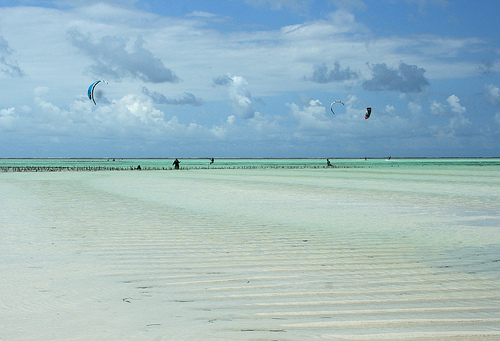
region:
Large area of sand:
[8, 168, 499, 339]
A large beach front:
[3, 168, 498, 336]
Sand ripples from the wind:
[122, 222, 499, 332]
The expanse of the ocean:
[2, 155, 496, 169]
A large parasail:
[85, 78, 102, 105]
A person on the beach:
[168, 157, 183, 167]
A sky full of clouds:
[3, 0, 497, 153]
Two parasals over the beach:
[322, 98, 378, 121]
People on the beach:
[134, 157, 351, 173]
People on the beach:
[86, 77, 388, 174]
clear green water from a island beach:
[5, 157, 497, 167]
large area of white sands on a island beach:
[4, 172, 496, 337]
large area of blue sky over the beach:
[2, 1, 497, 156]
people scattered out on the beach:
[105, 156, 398, 168]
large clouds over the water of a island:
[5, 76, 496, 142]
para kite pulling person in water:
[87, 78, 104, 104]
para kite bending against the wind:
[327, 100, 343, 115]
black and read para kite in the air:
[362, 106, 372, 118]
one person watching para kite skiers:
[172, 158, 179, 168]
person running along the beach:
[325, 158, 332, 165]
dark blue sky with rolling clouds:
[0, 0, 496, 178]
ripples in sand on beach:
[1, 154, 498, 339]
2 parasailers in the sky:
[74, 53, 428, 150]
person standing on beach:
[91, 140, 219, 180]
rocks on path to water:
[3, 155, 173, 194]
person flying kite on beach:
[242, 90, 403, 177]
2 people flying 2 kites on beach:
[65, 68, 230, 180]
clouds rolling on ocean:
[2, 4, 494, 241]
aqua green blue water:
[0, 133, 499, 185]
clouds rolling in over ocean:
[3, 16, 494, 166]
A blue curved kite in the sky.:
[89, 74, 104, 113]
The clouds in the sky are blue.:
[82, 34, 164, 74]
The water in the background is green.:
[48, 160, 94, 167]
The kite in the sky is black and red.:
[364, 105, 374, 121]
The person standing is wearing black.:
[170, 157, 185, 169]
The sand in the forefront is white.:
[121, 256, 251, 307]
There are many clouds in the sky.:
[137, 58, 320, 134]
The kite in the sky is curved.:
[322, 95, 350, 118]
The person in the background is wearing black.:
[323, 158, 336, 169]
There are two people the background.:
[103, 156, 123, 164]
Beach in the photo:
[108, 212, 276, 261]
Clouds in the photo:
[167, 30, 283, 97]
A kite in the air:
[66, 71, 111, 111]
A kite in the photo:
[316, 81, 394, 126]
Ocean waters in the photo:
[249, 150, 306, 170]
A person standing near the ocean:
[162, 150, 194, 177]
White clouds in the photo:
[135, 47, 212, 129]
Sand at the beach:
[33, 217, 113, 294]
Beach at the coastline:
[270, 177, 381, 207]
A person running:
[308, 147, 341, 179]